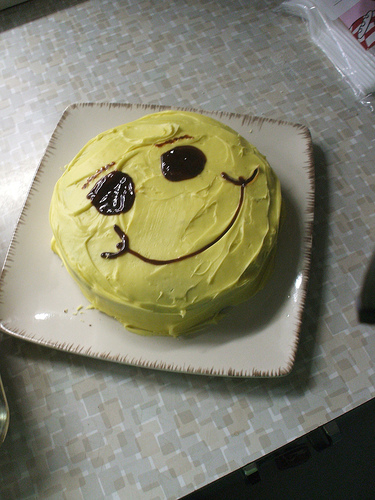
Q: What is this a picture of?
A: Cake.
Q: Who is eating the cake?
A: No one.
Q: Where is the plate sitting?
A: The counter.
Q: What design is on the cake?
A: Happy face.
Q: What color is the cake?
A: Yellow.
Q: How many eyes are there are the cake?
A: Two.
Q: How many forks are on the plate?
A: None.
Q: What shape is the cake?
A: Circle.